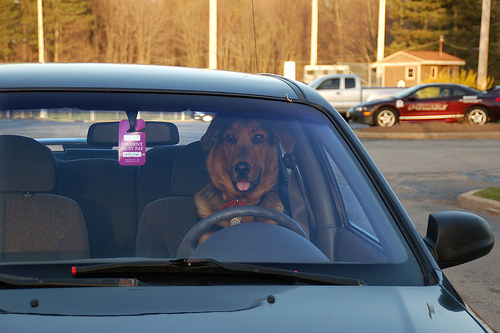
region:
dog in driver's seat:
[159, 88, 351, 274]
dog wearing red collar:
[183, 111, 288, 243]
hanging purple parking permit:
[107, 103, 161, 171]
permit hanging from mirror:
[69, 93, 214, 165]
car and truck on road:
[291, 66, 499, 141]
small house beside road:
[366, 52, 471, 105]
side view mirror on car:
[409, 182, 499, 299]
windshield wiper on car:
[63, 242, 371, 298]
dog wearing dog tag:
[213, 203, 252, 232]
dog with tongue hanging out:
[206, 123, 283, 205]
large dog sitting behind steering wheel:
[186, 108, 303, 253]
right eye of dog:
[224, 130, 239, 143]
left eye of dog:
[251, 131, 265, 144]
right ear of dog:
[197, 110, 226, 151]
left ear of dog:
[268, 113, 297, 153]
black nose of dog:
[233, 158, 253, 173]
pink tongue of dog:
[231, 180, 253, 192]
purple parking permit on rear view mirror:
[117, 117, 146, 166]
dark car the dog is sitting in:
[0, 63, 494, 332]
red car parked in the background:
[347, 78, 498, 126]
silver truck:
[307, 58, 407, 116]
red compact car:
[350, 81, 498, 141]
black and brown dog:
[192, 104, 321, 221]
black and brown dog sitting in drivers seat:
[5, 15, 496, 327]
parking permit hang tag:
[108, 110, 162, 175]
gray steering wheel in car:
[185, 208, 319, 265]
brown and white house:
[375, 28, 485, 95]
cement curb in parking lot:
[397, 126, 498, 158]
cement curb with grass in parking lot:
[456, 174, 498, 222]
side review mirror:
[415, 196, 497, 281]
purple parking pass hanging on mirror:
[116, 116, 150, 167]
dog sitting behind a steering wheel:
[192, 108, 301, 241]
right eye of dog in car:
[225, 131, 239, 143]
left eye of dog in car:
[253, 131, 265, 144]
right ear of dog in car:
[198, 112, 226, 152]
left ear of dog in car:
[263, 106, 294, 151]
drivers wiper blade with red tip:
[63, 255, 362, 287]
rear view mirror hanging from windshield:
[80, 108, 185, 147]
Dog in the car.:
[182, 104, 376, 258]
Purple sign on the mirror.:
[113, 112, 169, 176]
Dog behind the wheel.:
[170, 120, 327, 253]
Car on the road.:
[3, 58, 495, 280]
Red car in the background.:
[343, 70, 494, 121]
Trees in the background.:
[32, 5, 325, 67]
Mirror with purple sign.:
[85, 105, 197, 159]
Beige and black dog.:
[165, 120, 316, 242]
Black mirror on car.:
[418, 201, 498, 271]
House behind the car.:
[363, 29, 468, 89]